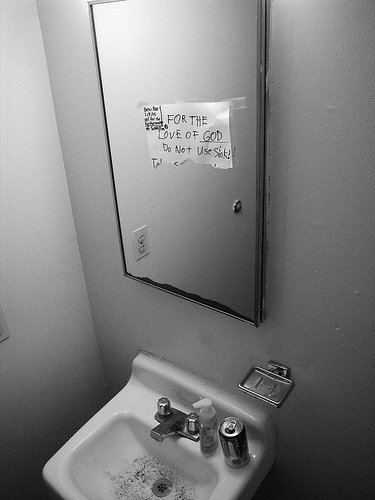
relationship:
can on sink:
[216, 416, 248, 467] [34, 346, 280, 498]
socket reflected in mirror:
[131, 224, 152, 262] [82, 2, 270, 327]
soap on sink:
[192, 396, 217, 456] [34, 346, 280, 498]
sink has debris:
[34, 346, 280, 498] [110, 456, 197, 496]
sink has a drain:
[34, 346, 280, 498] [151, 476, 175, 498]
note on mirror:
[138, 102, 233, 171] [82, 2, 270, 327]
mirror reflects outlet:
[82, 2, 270, 327] [131, 224, 152, 262]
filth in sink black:
[110, 456, 197, 496] [139, 456, 150, 478]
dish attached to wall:
[240, 363, 293, 408] [190, 313, 375, 421]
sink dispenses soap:
[34, 346, 280, 498] [192, 396, 217, 456]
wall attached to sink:
[190, 313, 375, 421] [34, 346, 280, 498]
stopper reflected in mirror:
[231, 200, 244, 215] [82, 2, 270, 327]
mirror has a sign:
[82, 2, 270, 327] [138, 102, 233, 171]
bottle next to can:
[192, 396, 217, 456] [216, 416, 248, 467]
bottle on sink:
[192, 396, 217, 456] [34, 346, 280, 498]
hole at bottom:
[151, 476, 175, 498] [130, 463, 201, 499]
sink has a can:
[34, 346, 280, 498] [216, 416, 248, 467]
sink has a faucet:
[34, 346, 280, 498] [150, 397, 201, 443]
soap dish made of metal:
[240, 363, 293, 408] [270, 373, 289, 389]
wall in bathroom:
[190, 313, 375, 421] [6, 3, 374, 498]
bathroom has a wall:
[6, 3, 374, 498] [190, 313, 375, 421]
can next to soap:
[216, 416, 248, 467] [251, 372, 280, 401]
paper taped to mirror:
[138, 102, 233, 171] [82, 2, 270, 327]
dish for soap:
[240, 363, 293, 408] [251, 372, 280, 401]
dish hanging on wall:
[240, 363, 293, 408] [190, 313, 375, 421]